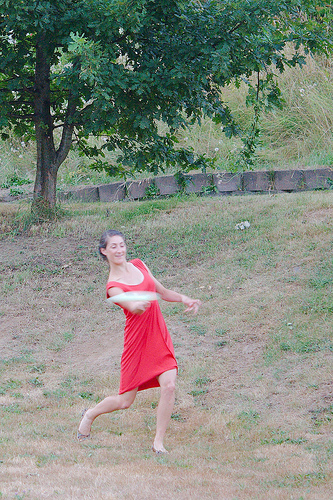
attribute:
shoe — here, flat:
[74, 411, 99, 445]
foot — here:
[70, 406, 105, 440]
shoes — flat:
[78, 410, 171, 455]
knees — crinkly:
[114, 370, 179, 411]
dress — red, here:
[104, 257, 179, 394]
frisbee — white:
[112, 292, 159, 305]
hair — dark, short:
[97, 224, 124, 260]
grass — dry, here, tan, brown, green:
[5, 204, 332, 498]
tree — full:
[3, 0, 332, 220]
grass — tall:
[3, 15, 332, 189]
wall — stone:
[57, 170, 332, 205]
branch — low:
[57, 22, 225, 164]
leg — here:
[150, 370, 175, 457]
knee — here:
[158, 373, 181, 394]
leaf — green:
[69, 30, 88, 48]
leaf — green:
[133, 113, 151, 130]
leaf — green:
[261, 40, 277, 52]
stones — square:
[60, 163, 332, 204]